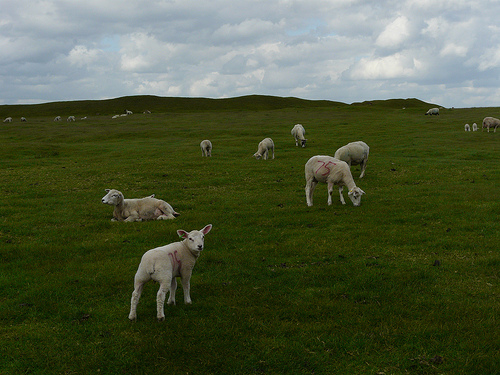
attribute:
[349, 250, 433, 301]
grass — green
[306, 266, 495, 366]
grass — in the picture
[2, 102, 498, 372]
grass — large, green